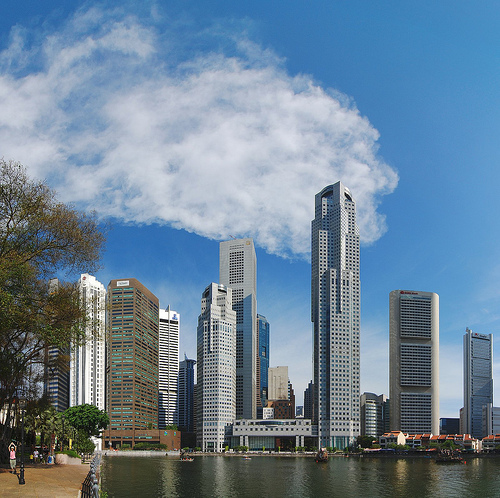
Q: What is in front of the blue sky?
A: A white cloud.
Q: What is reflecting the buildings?
A: A lake.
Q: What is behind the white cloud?
A: A blue sky.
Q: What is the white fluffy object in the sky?
A: A cloud.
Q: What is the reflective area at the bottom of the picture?
A: A lake.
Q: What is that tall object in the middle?
A: A skyscraper.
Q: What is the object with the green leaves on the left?
A: A tree.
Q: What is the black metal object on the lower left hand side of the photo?
A: A lamp post.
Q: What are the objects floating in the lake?
A: Boats.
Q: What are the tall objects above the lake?
A: Buildings.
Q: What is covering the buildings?
A: Windows.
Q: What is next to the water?
A: Pilings.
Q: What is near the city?
A: Dark water.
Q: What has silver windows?
A: The tall building.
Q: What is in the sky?
A: White clouds.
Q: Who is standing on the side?
A: A woman.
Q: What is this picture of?
A: A skyline.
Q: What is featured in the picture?
A: Several buildings.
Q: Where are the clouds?
A: In the sky.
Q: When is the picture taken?
A: During the day.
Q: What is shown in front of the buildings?
A: A body of water.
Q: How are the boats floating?
A: Along the water.